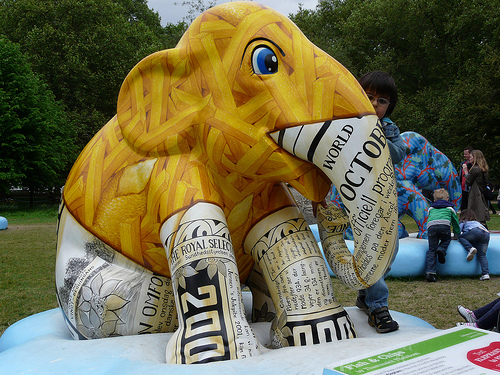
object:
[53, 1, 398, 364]
elephant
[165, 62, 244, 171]
pattern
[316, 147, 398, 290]
trunk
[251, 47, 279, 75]
eyes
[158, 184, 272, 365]
legs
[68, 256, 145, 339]
diaper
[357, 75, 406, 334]
child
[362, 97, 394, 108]
glasses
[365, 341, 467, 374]
sign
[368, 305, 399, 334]
shoe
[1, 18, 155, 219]
trees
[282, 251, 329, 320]
words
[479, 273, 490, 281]
shoes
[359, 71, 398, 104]
hair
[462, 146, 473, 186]
man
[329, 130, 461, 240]
sculpture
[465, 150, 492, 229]
woman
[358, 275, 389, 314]
jeans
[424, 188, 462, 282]
boy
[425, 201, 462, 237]
sweater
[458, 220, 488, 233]
shirt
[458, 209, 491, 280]
girl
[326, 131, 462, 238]
elephant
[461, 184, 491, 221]
coat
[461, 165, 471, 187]
shirt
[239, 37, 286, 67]
eyebrow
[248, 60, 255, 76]
eyelashes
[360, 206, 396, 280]
writing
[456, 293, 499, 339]
person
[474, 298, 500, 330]
pants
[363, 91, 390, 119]
face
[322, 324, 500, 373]
book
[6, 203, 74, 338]
lawn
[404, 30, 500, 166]
forest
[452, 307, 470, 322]
sole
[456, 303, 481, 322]
shoe